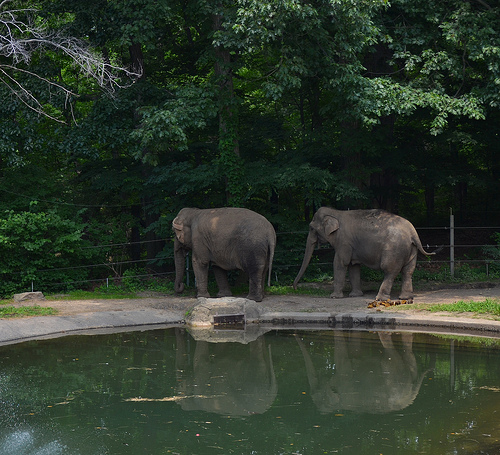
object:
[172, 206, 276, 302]
elephants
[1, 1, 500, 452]
zoo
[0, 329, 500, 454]
pond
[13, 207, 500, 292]
fence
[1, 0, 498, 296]
trees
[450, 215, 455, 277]
pole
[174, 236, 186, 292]
trunk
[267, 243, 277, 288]
tail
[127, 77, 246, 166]
leaves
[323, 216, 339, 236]
ears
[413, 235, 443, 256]
tail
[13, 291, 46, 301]
stone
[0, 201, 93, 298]
bush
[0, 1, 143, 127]
branches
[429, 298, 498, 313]
grass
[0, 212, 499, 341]
ground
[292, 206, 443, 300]
elephant